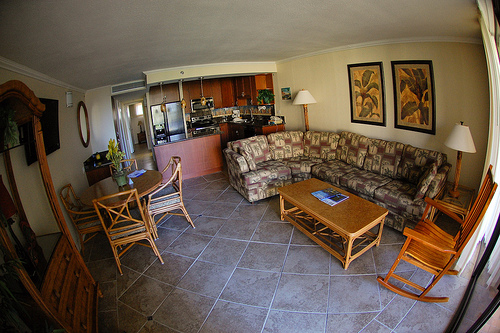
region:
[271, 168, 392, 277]
a wooden coffee table.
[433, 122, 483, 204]
a lamp on a table.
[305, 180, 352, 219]
books on top of a table.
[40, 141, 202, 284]
a dining room table set.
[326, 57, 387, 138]
a picture in a frame.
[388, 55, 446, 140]
a nice framed picture.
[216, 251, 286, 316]
a tile on the floor.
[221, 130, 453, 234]
a couch in a living room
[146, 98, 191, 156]
a metal refrigerator.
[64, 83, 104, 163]
a mirror on the wall.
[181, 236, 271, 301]
this is the floor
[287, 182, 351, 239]
this is the table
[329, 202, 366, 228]
the table is wooden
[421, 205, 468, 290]
this is a chair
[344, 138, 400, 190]
this is a couch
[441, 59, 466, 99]
this is the wall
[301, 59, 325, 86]
the wall is white in color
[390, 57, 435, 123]
this is a picture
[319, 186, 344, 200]
this is a book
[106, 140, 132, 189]
this is a flower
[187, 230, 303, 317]
the floors are tiled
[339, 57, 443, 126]
the paintings are hanged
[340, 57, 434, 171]
paintings above the couch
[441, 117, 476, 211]
the lamp is on table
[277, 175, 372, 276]
magazines on the table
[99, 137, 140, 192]
plant is on the table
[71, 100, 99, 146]
mirror is on the wall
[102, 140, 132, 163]
the flowers are yellow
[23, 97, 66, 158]
the tv is off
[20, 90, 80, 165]
the tv is black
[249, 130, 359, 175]
this is a sofa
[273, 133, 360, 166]
the sofa is empty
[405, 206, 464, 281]
this is a chair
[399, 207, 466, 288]
the chair is wooden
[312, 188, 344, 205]
this is a magazine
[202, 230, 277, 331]
this is a floor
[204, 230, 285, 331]
the floor is tiled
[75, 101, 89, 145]
this is a mirror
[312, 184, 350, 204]
the magazine is on the table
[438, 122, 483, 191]
this is a lampstand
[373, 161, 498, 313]
Wood rocking chair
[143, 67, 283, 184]
Kitchen with stainless steel appliances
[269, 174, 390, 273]
Wood coffee table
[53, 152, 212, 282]
Dining room set with bamboo chairs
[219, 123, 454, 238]
Sectional sofa with a palm tree motif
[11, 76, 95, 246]
Beige wall with a mirror and flat screen TV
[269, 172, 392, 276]
Coffee table with brochures on top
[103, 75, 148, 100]
White air vent grate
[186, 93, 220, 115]
Built in stainless steel microwave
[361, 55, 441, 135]
framed pictures on a wall